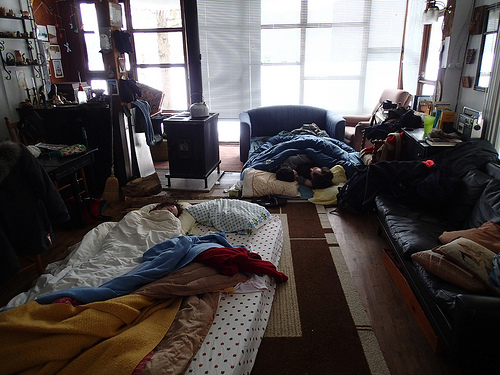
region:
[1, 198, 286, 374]
The mattress on the floor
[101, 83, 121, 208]
The broom made of straw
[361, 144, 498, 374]
The black couch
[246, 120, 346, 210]
Two people sleeping on pull out chair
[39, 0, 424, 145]
Windows where light is coming in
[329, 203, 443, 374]
Exposed hardwood floor near couch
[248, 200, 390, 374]
The rug in front of the couch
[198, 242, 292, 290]
The red blanket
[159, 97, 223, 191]
The wood burning stove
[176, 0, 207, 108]
Smoke pipe attached to the wood burning stove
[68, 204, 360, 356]
brown and cream color area rug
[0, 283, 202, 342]
gold full size blanket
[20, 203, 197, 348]
person lying in full size bed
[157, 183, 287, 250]
standard size pillow with pillowcase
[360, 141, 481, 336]
black vinyl sofa with three pillows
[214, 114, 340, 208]
two people lying in a standard chair sleeper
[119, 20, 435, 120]
several glass windows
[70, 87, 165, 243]
standard straw broom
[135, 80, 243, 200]
black wood heater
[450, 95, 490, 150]
compact radio with antenna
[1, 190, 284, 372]
Mattress is lying on floor.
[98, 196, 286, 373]
Sheet is polka dotted.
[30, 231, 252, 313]
The blanket is blue.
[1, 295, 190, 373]
The blanket is butterscotch colored.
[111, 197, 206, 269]
Someone is still sleeping.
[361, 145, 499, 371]
Couch is black leather.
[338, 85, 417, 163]
Chair is in far corner.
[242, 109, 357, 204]
Someone is sleeping on fold out bed.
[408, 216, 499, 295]
Pillows are tossed on couch.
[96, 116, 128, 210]
There's a broom leaning against some furniture.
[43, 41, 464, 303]
three people sleeping on floor in crowded room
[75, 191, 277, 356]
one person sleeping on floor on matress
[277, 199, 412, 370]
maroon and beige area rug in small apartment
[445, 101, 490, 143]
silver radio on desk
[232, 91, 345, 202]
two people sleeping on floor on fold out matress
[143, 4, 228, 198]
wood burning stove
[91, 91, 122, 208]
broom leaning against furniture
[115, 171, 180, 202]
wood for the wood burner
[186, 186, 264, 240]
polka dotted bed pillow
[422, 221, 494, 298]
couch pillow with two ducks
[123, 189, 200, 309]
Person laying on matress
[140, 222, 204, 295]
Blue blanket on bed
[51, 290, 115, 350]
Tan blanket on bed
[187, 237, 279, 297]
Red blanket on bed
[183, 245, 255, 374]
White sheets with prints on them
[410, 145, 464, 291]
Black couch on right side of room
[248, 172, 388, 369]
Large brown and tan area rug on floor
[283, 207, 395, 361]
Area rug on top of hardwood floors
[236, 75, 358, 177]
People sleeping under a blue sleeping bag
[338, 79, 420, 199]
Light brown chair near windows